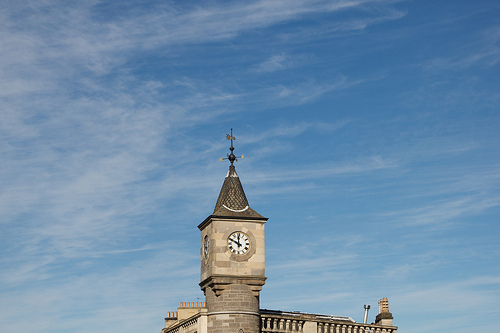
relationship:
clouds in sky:
[2, 2, 491, 332] [1, 0, 496, 331]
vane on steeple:
[192, 127, 314, 222] [197, 127, 269, 297]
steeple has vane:
[197, 127, 269, 297] [192, 127, 314, 222]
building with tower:
[159, 123, 404, 330] [202, 166, 274, 331]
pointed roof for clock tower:
[208, 167, 269, 218] [197, 218, 274, 311]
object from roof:
[338, 269, 398, 331] [273, 267, 396, 331]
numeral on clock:
[230, 228, 239, 239] [225, 229, 252, 257]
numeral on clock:
[240, 233, 245, 238] [225, 229, 252, 257]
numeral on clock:
[241, 244, 250, 251] [225, 229, 252, 257]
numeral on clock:
[230, 247, 238, 254] [225, 229, 252, 257]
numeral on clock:
[243, 241, 252, 246] [225, 229, 252, 257]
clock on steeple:
[227, 231, 250, 253] [197, 127, 269, 297]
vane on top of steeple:
[226, 134, 237, 141] [197, 127, 269, 297]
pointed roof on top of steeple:
[212, 165, 270, 219] [197, 127, 269, 297]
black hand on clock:
[228, 237, 242, 247] [223, 226, 253, 254]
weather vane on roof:
[218, 126, 243, 163] [160, 165, 398, 332]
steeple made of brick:
[197, 127, 269, 297] [195, 261, 270, 309]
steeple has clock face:
[197, 127, 269, 297] [227, 230, 252, 257]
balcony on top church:
[224, 263, 413, 331] [157, 126, 395, 329]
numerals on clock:
[231, 233, 249, 253] [224, 229, 256, 256]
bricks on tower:
[212, 220, 265, 277] [184, 123, 286, 330]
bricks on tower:
[212, 220, 231, 232] [184, 123, 286, 330]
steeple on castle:
[211, 170, 254, 220] [147, 122, 402, 330]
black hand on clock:
[232, 227, 243, 244] [222, 226, 253, 261]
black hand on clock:
[224, 233, 242, 247] [222, 226, 253, 261]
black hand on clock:
[228, 237, 242, 247] [222, 226, 253, 261]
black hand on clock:
[237, 235, 240, 247] [222, 226, 253, 261]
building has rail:
[159, 128, 397, 332] [254, 312, 399, 330]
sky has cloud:
[1, 0, 496, 331] [397, 183, 498, 231]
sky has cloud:
[1, 0, 496, 331] [427, 50, 487, 80]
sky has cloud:
[1, 0, 496, 331] [392, 271, 496, 316]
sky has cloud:
[1, 0, 496, 331] [254, 43, 299, 78]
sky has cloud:
[1, 0, 496, 331] [280, 224, 364, 272]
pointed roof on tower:
[212, 165, 270, 219] [197, 162, 269, 331]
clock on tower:
[227, 230, 251, 254] [198, 210, 264, 330]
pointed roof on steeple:
[212, 165, 270, 219] [198, 126, 268, 331]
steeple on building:
[197, 127, 269, 297] [165, 227, 394, 330]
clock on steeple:
[205, 217, 270, 282] [198, 216, 276, 326]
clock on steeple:
[227, 230, 251, 254] [198, 126, 268, 331]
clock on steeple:
[204, 235, 210, 260] [198, 126, 268, 331]